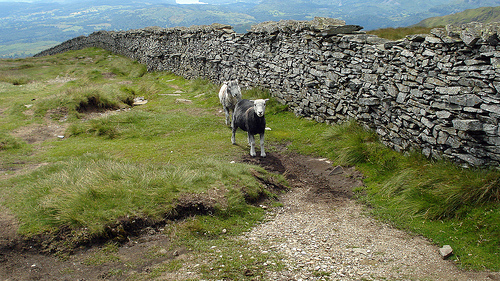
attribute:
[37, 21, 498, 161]
wall — stone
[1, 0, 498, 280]
grass — tall, green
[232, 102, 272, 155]
sheep — white, black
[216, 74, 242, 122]
sheep — white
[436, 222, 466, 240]
grass — green, short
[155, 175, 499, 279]
gravel — tan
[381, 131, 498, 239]
grass — tall, green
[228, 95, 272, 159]
sheep — white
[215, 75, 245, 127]
sheep — white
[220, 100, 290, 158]
sheep — black, white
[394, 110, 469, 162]
ground — gray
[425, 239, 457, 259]
rock — big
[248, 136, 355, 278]
ground — brown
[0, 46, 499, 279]
ground — green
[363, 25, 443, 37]
grass — green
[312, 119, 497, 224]
grass — long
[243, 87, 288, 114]
grass — long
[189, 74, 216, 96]
grass — long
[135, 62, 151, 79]
grass — long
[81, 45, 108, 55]
grass — long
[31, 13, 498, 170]
wall — rock, stone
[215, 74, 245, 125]
goat — white